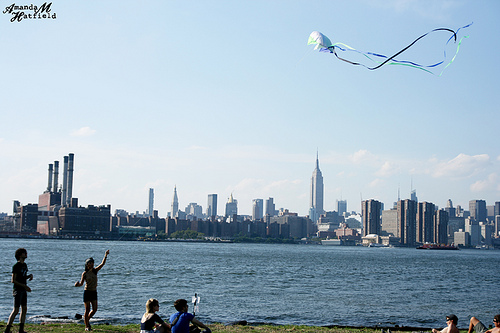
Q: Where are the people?
A: On the beach.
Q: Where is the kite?
A: Over the water.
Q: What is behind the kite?
A: Streamers.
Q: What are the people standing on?
A: Grass.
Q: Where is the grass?
A: Next to the water.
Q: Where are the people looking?
A: Up at the kite.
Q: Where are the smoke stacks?
A: On a building.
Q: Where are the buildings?
A: In the city skyline.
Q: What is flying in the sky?
A: Kite.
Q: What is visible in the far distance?
A: City skyline.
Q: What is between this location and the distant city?
A: Lake.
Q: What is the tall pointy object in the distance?
A: Skyscraper.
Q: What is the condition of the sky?
A: Very slightly cloudy.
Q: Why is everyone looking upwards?
A: To see the kites.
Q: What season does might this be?
A: Summer.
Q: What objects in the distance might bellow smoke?
A: Smoke Stacks.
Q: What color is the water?
A: Blue.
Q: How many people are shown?
A: 6.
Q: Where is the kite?
A: In the air.